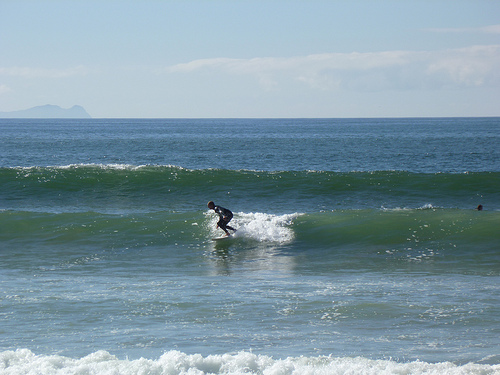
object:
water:
[0, 117, 500, 244]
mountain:
[0, 103, 96, 119]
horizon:
[0, 114, 500, 122]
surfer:
[206, 200, 237, 238]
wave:
[0, 204, 500, 247]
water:
[0, 274, 500, 375]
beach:
[0, 215, 500, 375]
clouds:
[416, 23, 500, 34]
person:
[473, 203, 484, 212]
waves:
[0, 162, 500, 195]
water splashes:
[209, 208, 302, 242]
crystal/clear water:
[0, 272, 500, 343]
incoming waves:
[0, 349, 500, 375]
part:
[153, 14, 227, 53]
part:
[252, 212, 294, 243]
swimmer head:
[207, 200, 216, 210]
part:
[218, 207, 225, 217]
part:
[356, 273, 495, 349]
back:
[216, 205, 230, 214]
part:
[278, 53, 364, 73]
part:
[251, 116, 500, 176]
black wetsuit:
[213, 204, 235, 233]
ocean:
[0, 116, 500, 375]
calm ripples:
[0, 117, 500, 160]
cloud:
[159, 41, 498, 98]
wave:
[0, 342, 500, 375]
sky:
[0, 0, 500, 120]